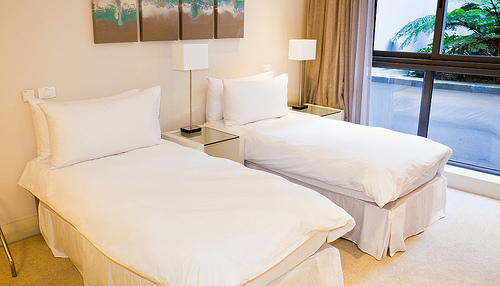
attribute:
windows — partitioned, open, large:
[370, 1, 500, 178]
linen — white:
[19, 140, 355, 284]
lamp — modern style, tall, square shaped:
[169, 40, 210, 140]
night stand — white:
[165, 125, 243, 164]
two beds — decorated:
[16, 70, 452, 285]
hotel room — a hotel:
[1, 0, 500, 285]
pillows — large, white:
[25, 83, 165, 172]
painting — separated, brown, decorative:
[89, 1, 248, 47]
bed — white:
[17, 83, 360, 282]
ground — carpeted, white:
[1, 185, 498, 284]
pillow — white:
[38, 81, 163, 170]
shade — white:
[172, 43, 209, 73]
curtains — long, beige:
[305, 1, 375, 127]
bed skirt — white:
[246, 157, 448, 262]